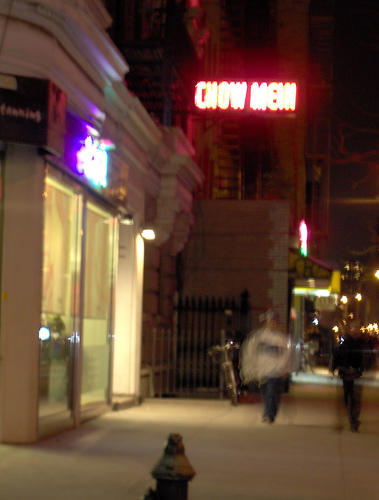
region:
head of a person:
[248, 302, 286, 335]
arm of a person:
[232, 335, 255, 385]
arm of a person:
[271, 335, 309, 376]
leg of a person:
[255, 378, 292, 415]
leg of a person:
[333, 376, 365, 418]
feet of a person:
[248, 408, 282, 434]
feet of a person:
[344, 419, 374, 436]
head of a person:
[335, 314, 357, 339]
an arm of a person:
[233, 330, 278, 383]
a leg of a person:
[258, 377, 291, 409]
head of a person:
[262, 301, 291, 329]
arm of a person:
[238, 333, 250, 372]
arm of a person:
[266, 346, 296, 373]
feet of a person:
[339, 421, 369, 430]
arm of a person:
[318, 338, 349, 379]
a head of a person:
[259, 289, 287, 326]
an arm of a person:
[236, 330, 254, 366]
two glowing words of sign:
[193, 80, 298, 108]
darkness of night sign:
[320, 2, 376, 256]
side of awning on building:
[291, 248, 340, 293]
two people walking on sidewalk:
[241, 309, 369, 426]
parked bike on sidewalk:
[210, 342, 243, 403]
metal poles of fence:
[154, 295, 250, 394]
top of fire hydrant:
[143, 433, 194, 499]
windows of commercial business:
[36, 184, 119, 424]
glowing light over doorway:
[114, 215, 154, 400]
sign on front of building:
[1, 72, 134, 212]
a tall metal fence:
[181, 235, 291, 434]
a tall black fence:
[159, 274, 282, 429]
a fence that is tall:
[175, 276, 288, 400]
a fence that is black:
[163, 265, 269, 402]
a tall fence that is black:
[135, 249, 268, 382]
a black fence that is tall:
[145, 256, 235, 385]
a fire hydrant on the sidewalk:
[99, 412, 206, 487]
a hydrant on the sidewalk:
[113, 408, 222, 480]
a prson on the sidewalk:
[206, 300, 376, 453]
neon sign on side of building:
[191, 76, 299, 116]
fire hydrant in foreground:
[134, 429, 201, 499]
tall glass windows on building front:
[33, 169, 118, 430]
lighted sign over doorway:
[66, 126, 122, 193]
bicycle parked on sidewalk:
[203, 337, 246, 410]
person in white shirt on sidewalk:
[234, 301, 295, 430]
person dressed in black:
[321, 328, 374, 435]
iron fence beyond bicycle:
[147, 279, 257, 407]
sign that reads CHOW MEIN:
[185, 75, 301, 115]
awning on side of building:
[285, 243, 345, 301]